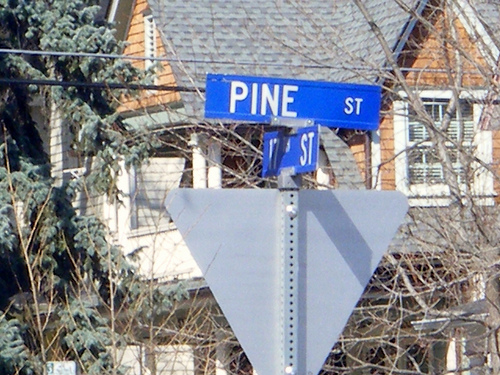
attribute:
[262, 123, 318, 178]
sign — blue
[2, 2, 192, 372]
leaves — green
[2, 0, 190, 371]
tree — green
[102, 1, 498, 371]
building — orange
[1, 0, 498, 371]
tree — bare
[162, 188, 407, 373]
sign — gray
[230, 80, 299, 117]
pine — name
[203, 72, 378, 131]
sign — blue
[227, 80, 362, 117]
lettering — white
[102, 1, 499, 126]
roof — gray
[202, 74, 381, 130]
street sign — blue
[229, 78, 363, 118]
text — white, print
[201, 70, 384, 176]
sign — blue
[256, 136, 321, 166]
sign — blue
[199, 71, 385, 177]
signs — blue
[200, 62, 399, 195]
signs — blue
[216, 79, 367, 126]
text print — white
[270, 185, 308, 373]
pole — metal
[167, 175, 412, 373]
sign — triangular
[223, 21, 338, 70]
roof — gray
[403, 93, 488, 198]
windows — white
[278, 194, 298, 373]
pole — gray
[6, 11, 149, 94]
leaves — green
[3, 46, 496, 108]
power lines — black, a pair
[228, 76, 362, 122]
writing — white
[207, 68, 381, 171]
sign — blue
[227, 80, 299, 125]
word — pine, white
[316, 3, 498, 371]
tree — dead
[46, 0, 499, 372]
house — brown, background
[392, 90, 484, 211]
window — white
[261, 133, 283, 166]
number — 17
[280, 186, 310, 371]
pole — silver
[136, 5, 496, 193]
roof — gray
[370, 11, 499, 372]
tree — gray